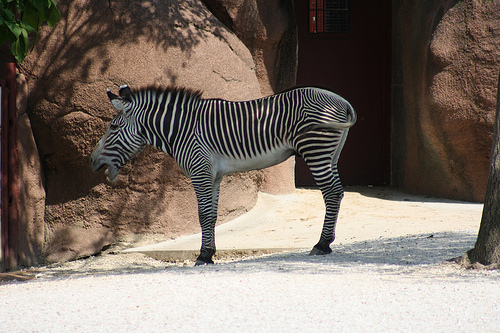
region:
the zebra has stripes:
[59, 54, 469, 260]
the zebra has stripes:
[140, 119, 399, 326]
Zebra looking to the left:
[83, 70, 397, 275]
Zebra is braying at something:
[78, 89, 163, 205]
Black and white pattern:
[207, 95, 261, 165]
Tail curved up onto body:
[290, 84, 373, 159]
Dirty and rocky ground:
[377, 201, 449, 263]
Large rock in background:
[420, 27, 497, 152]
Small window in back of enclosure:
[302, 4, 360, 44]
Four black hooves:
[190, 234, 340, 259]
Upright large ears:
[97, 82, 144, 119]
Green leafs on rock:
[7, 5, 56, 54]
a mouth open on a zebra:
[88, 150, 134, 186]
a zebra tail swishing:
[292, 84, 369, 146]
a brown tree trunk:
[470, 80, 499, 270]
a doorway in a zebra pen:
[292, 0, 410, 194]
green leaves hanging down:
[1, 3, 64, 62]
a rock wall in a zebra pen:
[389, 7, 496, 194]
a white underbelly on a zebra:
[210, 133, 305, 176]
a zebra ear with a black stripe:
[102, 86, 130, 116]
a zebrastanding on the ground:
[77, 69, 376, 263]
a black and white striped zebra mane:
[120, 83, 210, 101]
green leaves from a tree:
[0, 1, 74, 76]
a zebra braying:
[85, 79, 361, 269]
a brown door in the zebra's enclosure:
[285, 0, 397, 197]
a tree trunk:
[447, 61, 497, 270]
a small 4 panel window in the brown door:
[292, 0, 333, 45]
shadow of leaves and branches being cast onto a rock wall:
[10, 0, 240, 85]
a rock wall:
[380, 0, 490, 200]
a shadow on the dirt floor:
[33, 220, 490, 289]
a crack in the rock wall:
[21, 101, 118, 228]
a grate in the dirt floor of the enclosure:
[0, 259, 55, 294]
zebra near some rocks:
[80, 66, 372, 270]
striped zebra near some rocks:
[75, 55, 385, 263]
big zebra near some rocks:
[60, 65, 366, 288]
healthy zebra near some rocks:
[65, 31, 410, 276]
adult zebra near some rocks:
[55, 56, 374, 292]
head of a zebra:
[77, 81, 159, 191]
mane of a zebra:
[124, 69, 209, 109]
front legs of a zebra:
[175, 167, 248, 281]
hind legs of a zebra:
[294, 153, 365, 259]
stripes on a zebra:
[187, 101, 312, 150]